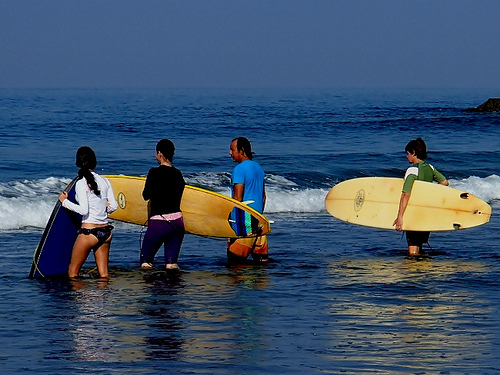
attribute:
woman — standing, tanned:
[53, 143, 121, 288]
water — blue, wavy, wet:
[1, 100, 500, 374]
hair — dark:
[72, 145, 104, 200]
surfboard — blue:
[28, 173, 77, 282]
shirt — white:
[58, 170, 122, 226]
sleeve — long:
[101, 177, 122, 217]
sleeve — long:
[61, 180, 93, 217]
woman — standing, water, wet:
[134, 136, 190, 273]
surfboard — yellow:
[82, 173, 275, 245]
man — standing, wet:
[222, 133, 274, 267]